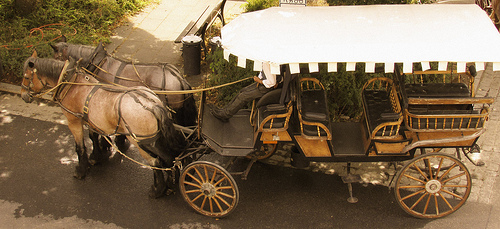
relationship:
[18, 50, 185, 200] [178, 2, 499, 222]
horse pulling wagon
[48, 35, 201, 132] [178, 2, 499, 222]
horse pulling wagon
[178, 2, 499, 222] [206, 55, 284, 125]
wagon has driver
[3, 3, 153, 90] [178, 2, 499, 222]
foliage to left of wagon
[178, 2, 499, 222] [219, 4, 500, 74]
wagon has canopy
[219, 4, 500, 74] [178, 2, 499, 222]
canopy over wagon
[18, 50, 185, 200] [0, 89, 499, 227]
horse on road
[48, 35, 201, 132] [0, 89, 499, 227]
horse on road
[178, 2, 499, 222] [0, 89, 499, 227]
wagon on road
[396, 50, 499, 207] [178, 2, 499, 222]
walkway to right of wagon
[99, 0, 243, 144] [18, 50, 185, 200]
walkway behind horse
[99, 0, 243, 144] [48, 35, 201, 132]
walkway behind horse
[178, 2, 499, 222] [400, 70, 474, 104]
wagon has back seat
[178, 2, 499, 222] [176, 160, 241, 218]
wagon has left wheel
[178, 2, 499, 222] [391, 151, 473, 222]
wagon has left wheel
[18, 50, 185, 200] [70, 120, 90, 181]
horse has leg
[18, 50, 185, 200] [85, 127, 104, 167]
horse has leg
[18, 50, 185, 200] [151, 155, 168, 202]
horse has leg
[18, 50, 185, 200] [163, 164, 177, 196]
horse has leg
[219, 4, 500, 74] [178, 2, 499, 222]
canopy on wagon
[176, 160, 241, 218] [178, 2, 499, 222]
left wheel front of wagon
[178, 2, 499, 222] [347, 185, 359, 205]
wagon has step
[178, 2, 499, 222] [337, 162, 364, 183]
wagon has step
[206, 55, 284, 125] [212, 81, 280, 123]
driver has bottom half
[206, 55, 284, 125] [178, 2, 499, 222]
driver in wagon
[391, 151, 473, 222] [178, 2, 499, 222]
left wheel back of wagon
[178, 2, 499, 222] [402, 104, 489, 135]
wagon has back seat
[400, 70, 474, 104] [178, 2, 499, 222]
back seat inside wagon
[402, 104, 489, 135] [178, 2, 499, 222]
back seat inside wagon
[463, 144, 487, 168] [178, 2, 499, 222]
foot stool on back of wagon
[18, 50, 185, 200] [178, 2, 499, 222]
horse in front of wagon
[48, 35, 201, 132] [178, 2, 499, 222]
horse in front of wagon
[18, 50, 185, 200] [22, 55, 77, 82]
horse has mane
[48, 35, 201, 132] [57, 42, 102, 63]
horse has mane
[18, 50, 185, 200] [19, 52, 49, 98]
horse has bridle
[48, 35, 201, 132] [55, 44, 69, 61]
horse has bridle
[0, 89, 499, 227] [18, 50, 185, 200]
road near horse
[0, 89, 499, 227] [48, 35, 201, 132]
road near horse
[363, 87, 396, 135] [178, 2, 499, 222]
seat on wagon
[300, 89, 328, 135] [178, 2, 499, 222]
seat on wagon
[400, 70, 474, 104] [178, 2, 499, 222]
back seat on wagon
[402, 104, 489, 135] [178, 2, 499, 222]
back seat on wagon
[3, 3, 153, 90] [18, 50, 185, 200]
foliage next to horse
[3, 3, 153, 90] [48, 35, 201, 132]
foliage next to horse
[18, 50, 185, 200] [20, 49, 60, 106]
horse has head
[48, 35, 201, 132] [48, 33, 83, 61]
horse has head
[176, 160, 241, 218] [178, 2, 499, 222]
left wheel on wagon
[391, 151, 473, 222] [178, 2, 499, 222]
left wheel on wagon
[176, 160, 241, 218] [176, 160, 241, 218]
left wheel has left wheel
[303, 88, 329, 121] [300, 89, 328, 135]
cushion on seat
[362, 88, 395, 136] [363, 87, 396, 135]
cushion on seat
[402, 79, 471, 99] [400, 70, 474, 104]
cushion on back seat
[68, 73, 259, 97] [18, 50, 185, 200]
rope attached to horse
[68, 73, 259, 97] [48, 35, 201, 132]
rope attached to horse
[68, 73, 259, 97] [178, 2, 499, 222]
rope pulls wagon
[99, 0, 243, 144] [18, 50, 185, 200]
walkway to right of horse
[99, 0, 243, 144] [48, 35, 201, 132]
walkway to right of horse